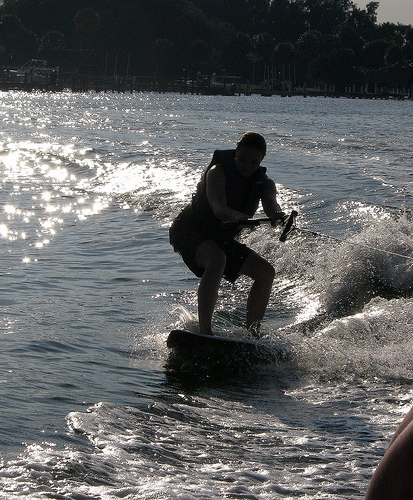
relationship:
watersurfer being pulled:
[171, 135, 299, 342] [272, 197, 349, 255]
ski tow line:
[275, 201, 412, 283] [278, 210, 411, 254]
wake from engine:
[269, 194, 410, 418] [372, 207, 412, 397]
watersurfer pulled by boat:
[171, 135, 299, 342] [275, 201, 412, 283]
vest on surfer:
[188, 150, 283, 228] [171, 135, 299, 342]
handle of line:
[279, 209, 306, 245] [278, 210, 411, 254]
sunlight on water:
[18, 101, 131, 259] [19, 88, 167, 304]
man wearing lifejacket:
[171, 135, 299, 342] [188, 150, 283, 228]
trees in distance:
[2, 3, 403, 66] [47, 12, 394, 53]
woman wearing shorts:
[171, 135, 299, 342] [170, 208, 252, 278]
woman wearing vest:
[171, 135, 299, 342] [188, 150, 283, 228]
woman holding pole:
[171, 135, 299, 342] [272, 197, 349, 255]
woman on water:
[171, 135, 299, 342] [19, 88, 167, 304]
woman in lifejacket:
[171, 135, 299, 342] [188, 150, 283, 228]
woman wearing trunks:
[171, 135, 299, 342] [170, 208, 252, 278]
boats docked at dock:
[9, 55, 401, 97] [5, 73, 411, 100]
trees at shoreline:
[4, 1, 400, 82] [2, 3, 403, 66]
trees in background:
[2, 3, 403, 66] [0, 3, 397, 191]